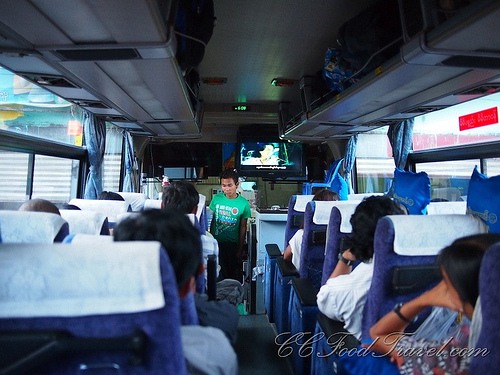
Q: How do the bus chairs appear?
A: Like blue seats with a white cloth on them.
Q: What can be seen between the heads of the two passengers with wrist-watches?
A: A blue seat with a white cloth.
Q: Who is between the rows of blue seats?
A: A man, wearing green, is in the aisle.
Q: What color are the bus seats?
A: Blue.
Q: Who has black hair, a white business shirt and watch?
A: A man sitting in a bus seat.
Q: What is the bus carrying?
A: The bus has people in it.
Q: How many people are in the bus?
A: Ten.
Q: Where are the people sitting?
A: On the bus.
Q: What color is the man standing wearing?
A: Green.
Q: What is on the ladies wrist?
A: Watch.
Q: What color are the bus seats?
A: Blue.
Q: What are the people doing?
A: Riding the bus.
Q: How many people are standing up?
A: One.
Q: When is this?
A: Daytime.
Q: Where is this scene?
A: On a bus.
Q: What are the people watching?
A: Television.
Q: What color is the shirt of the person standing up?
A: Green.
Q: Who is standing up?
A: A boy.